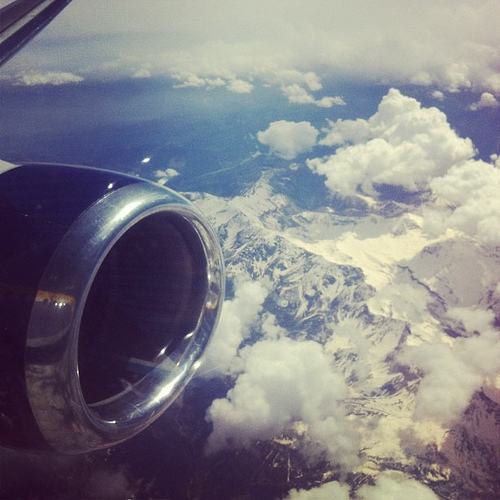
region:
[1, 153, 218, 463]
silver airplane engine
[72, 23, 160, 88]
white clouds in blue sky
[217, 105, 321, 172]
white clouds in blue sky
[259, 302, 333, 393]
white clouds in blue sky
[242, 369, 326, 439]
white clouds in blue sky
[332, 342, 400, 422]
white clouds in blue sky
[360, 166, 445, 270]
white clouds in blue sky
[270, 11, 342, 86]
white clouds in blue sky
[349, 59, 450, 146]
white clouds in blue sky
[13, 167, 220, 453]
shiny plane engine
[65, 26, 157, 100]
white clouds in blue sky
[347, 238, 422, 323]
white clouds in blue sky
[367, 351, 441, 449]
white clouds in blue sky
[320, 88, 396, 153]
white clouds in blue sky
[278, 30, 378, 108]
white clouds in blue sky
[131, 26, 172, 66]
white clouds in blue sky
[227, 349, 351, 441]
this is a cloud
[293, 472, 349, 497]
this is a cloud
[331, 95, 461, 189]
this is a cloud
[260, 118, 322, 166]
this is a cloud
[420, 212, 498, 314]
this is a cloud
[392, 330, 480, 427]
this is a cloud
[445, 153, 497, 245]
this is a cloud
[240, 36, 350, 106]
this is a cloud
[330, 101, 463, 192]
white fluffy clouds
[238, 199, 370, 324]
white and black mountain top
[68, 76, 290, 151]
a wooded forest area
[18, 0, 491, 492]
ground below a airplane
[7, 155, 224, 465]
a engine on a plane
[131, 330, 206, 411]
reflection on the rim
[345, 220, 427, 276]
a snowy valley below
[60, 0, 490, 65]
white cloudy sky's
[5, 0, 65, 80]
part of a plane wing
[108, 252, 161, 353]
inside of the engine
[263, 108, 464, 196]
The clouds are white.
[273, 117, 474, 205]
The clouds are fluffy.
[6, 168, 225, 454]
The plane engine is blue and silver.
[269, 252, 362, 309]
The mountains have snow on their peaks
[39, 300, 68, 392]
The trim of the plane engine is chrome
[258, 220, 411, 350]
The mountain is massive.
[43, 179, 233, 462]
The plane engine is shaped in a circle.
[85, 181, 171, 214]
Light is shining on the engine.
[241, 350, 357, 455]
The cloudnis white and thin.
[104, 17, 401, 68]
The cloud is white and heavy.